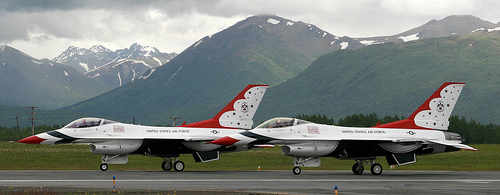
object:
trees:
[448, 113, 499, 144]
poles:
[31, 107, 36, 136]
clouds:
[0, 0, 500, 60]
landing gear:
[162, 157, 180, 161]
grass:
[0, 139, 498, 170]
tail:
[178, 82, 269, 129]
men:
[70, 120, 102, 128]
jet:
[206, 82, 478, 176]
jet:
[15, 84, 270, 172]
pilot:
[273, 120, 299, 128]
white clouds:
[166, 25, 185, 36]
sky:
[0, 0, 499, 61]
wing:
[192, 151, 220, 163]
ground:
[0, 169, 500, 192]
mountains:
[0, 14, 499, 127]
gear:
[370, 163, 383, 175]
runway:
[0, 168, 500, 194]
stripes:
[32, 131, 76, 144]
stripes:
[211, 132, 268, 146]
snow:
[265, 18, 280, 25]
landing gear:
[354, 156, 377, 164]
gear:
[99, 163, 108, 171]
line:
[0, 178, 500, 182]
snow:
[398, 33, 420, 43]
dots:
[237, 122, 240, 125]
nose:
[19, 129, 59, 144]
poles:
[15, 114, 19, 140]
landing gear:
[294, 156, 320, 167]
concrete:
[0, 187, 238, 194]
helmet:
[276, 119, 281, 124]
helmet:
[82, 119, 86, 123]